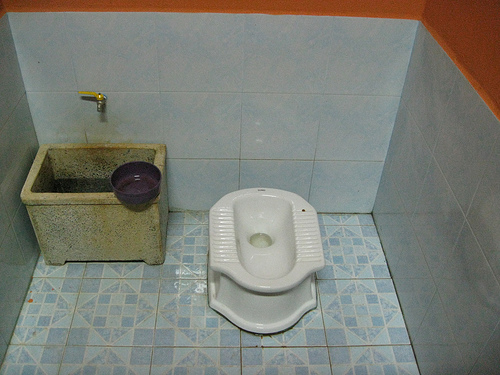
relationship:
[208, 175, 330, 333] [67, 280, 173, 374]
toilet above floor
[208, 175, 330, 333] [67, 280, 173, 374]
toilet on floor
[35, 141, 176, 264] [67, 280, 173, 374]
basin above floor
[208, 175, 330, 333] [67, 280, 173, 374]
toilet near floor